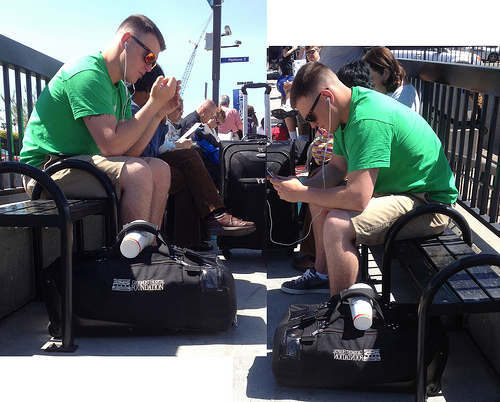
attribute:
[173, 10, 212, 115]
crane — tall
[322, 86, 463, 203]
shirt — green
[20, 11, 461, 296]
people — group 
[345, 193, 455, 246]
shorts — tan, brown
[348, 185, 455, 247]
shorts — cargo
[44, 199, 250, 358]
bag — black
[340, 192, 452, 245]
shorts — khaki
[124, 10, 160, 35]
hair — short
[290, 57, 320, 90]
hair — short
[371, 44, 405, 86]
hair — short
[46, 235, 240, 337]
bag — black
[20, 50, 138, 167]
shirt — green 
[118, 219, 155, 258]
cup — paper